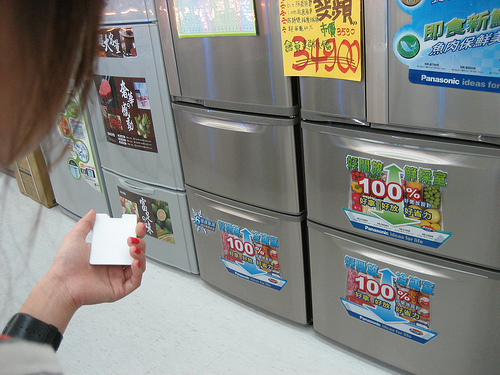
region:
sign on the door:
[320, 172, 463, 257]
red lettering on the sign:
[281, 4, 371, 92]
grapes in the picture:
[421, 179, 437, 210]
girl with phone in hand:
[63, 226, 155, 269]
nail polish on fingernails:
[130, 228, 144, 270]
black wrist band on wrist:
[8, 317, 65, 347]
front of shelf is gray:
[173, 106, 299, 213]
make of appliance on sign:
[421, 63, 470, 97]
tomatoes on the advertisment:
[352, 193, 365, 213]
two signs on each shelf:
[324, 149, 447, 353]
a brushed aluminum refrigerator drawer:
[181, 182, 311, 329]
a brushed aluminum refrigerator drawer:
[303, 220, 498, 373]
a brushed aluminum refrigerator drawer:
[298, 118, 498, 272]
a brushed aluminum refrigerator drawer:
[170, 100, 301, 215]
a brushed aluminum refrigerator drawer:
[99, 168, 199, 277]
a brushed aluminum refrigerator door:
[294, 0, 499, 144]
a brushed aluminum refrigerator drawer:
[152, 2, 299, 118]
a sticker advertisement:
[213, 219, 287, 294]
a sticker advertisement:
[336, 254, 438, 345]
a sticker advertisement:
[340, 155, 450, 250]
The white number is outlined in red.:
[223, 234, 235, 255]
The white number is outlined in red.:
[233, 233, 245, 257]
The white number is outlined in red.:
[243, 237, 256, 262]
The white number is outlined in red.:
[348, 268, 368, 298]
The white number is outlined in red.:
[365, 276, 381, 301]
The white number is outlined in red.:
[379, 280, 399, 304]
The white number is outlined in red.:
[358, 173, 373, 198]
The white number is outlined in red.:
[368, 176, 387, 202]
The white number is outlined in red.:
[384, 176, 404, 205]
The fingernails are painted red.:
[65, 200, 159, 302]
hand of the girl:
[68, 195, 184, 315]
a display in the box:
[327, 213, 454, 364]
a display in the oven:
[310, 118, 496, 233]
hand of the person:
[7, 299, 80, 353]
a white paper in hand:
[73, 203, 206, 322]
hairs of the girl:
[7, 27, 132, 171]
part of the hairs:
[11, 19, 122, 139]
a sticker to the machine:
[224, 206, 299, 284]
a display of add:
[353, 239, 488, 359]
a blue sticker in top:
[402, 14, 495, 91]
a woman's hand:
[8, 181, 185, 370]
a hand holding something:
[4, 185, 179, 355]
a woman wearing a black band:
[7, 188, 167, 365]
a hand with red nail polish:
[53, 188, 162, 328]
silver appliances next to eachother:
[171, 3, 491, 307]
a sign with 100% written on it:
[326, 137, 476, 249]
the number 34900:
[280, 22, 385, 92]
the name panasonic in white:
[393, 66, 498, 100]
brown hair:
[1, 0, 106, 190]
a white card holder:
[88, 203, 143, 278]